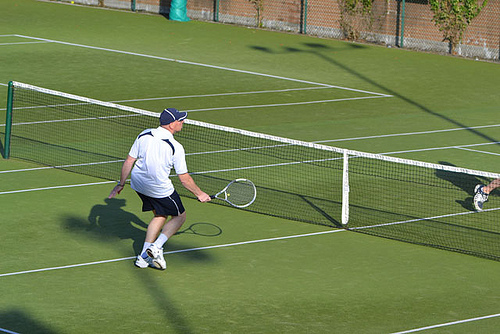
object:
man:
[108, 107, 212, 269]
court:
[0, 0, 500, 334]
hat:
[159, 108, 189, 125]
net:
[7, 81, 500, 262]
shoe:
[472, 183, 489, 211]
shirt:
[128, 126, 188, 199]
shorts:
[135, 189, 186, 216]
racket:
[197, 179, 257, 209]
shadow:
[59, 197, 223, 267]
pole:
[400, 0, 404, 47]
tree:
[428, 0, 487, 54]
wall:
[156, 0, 499, 61]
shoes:
[135, 243, 166, 270]